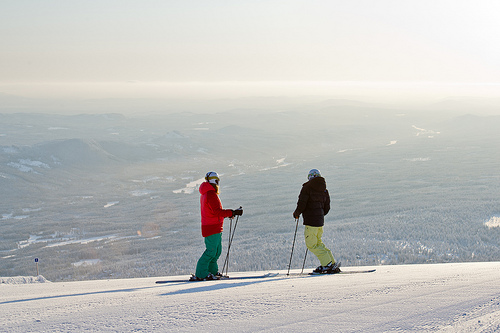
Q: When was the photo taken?
A: Winter.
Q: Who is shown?
A: Skiers.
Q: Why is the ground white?
A: Snow.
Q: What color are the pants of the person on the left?
A: Green.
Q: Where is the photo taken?
A: Mountains.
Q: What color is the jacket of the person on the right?
A: Black.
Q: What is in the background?
A: Valley.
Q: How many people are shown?
A: Two.